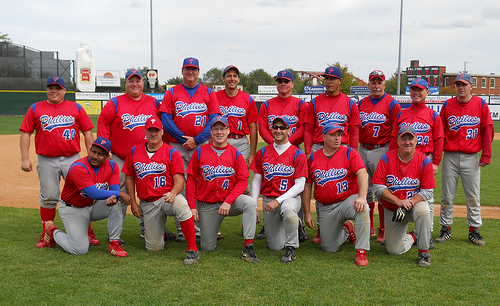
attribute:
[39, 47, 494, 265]
players — standing, looking, red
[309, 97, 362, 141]
uniform — red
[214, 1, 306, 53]
sky — blue, grey, clear, white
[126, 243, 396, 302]
field — green